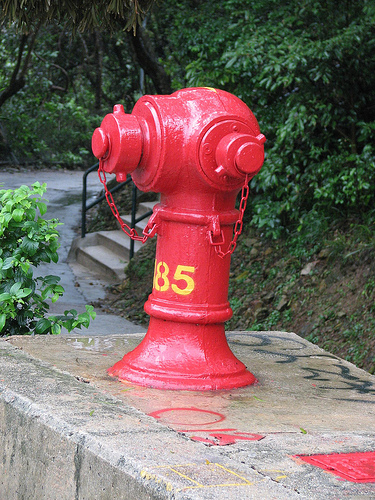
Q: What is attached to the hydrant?
A: Chain.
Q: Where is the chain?
A: Attached to the hydrant.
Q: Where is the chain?
A: Attached to the hydrant.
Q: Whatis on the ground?
A: Graffiti.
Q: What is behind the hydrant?
A: Green leaves.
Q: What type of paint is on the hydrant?
A: Bright red.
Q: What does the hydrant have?
A: Red chains.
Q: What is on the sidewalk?
A: A fire hydrant.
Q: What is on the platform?
A: Black graffiti.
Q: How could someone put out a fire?
A: Fire hydrant.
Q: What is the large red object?
A: Fire hydrant.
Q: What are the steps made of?
A: Cement.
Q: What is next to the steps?
A: Railing.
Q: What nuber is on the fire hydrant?
A: 85.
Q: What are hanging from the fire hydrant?
A: Red chains .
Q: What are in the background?
A: Green trees and bushes.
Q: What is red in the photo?
A: The fire hydrant.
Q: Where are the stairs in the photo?
A: Behind the fire hydrant.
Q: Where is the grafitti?
A: On the ground.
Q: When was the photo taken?
A: In the day time.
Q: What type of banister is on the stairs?
A: Black metal banister.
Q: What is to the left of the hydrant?
A: A green bush.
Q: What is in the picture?
A: A fire hydrant.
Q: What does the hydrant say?
A: 85.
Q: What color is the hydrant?
A: Red.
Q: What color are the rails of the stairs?
A: Black.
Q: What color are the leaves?
A: Green.